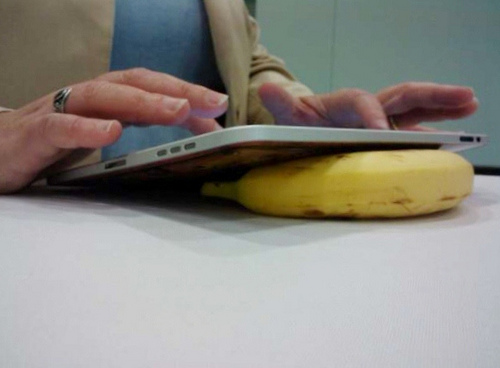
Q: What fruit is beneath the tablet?
A: A banana.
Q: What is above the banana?
A: A tablet device.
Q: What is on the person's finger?
A: A ring.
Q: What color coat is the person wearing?
A: Tan.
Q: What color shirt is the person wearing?
A: Blue.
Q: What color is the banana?
A: Yellow.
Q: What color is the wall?
A: Green.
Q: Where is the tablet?
A: On the banana.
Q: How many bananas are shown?
A: 1.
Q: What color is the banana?
A: Yellow.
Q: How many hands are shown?
A: 2.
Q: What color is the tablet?
A: Silver.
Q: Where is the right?
A: Person's right ring finger.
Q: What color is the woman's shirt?
A: Blue.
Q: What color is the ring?
A: Silver.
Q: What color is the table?
A: White.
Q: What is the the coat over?
A: The undershirt.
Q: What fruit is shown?
A: A banana.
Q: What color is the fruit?
A: Yellow.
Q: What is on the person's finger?
A: A ring.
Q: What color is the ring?
A: Silver.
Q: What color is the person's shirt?
A: Blue.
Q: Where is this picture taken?
A: An office.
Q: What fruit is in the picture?
A: Banana.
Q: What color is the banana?
A: Yellow.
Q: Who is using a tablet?
A: A woman.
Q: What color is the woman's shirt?
A: Blue.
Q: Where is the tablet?
A: On the banana.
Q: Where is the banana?
A: Under the tablet.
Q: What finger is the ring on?
A: The ring finger.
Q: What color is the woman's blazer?
A: Khaki.